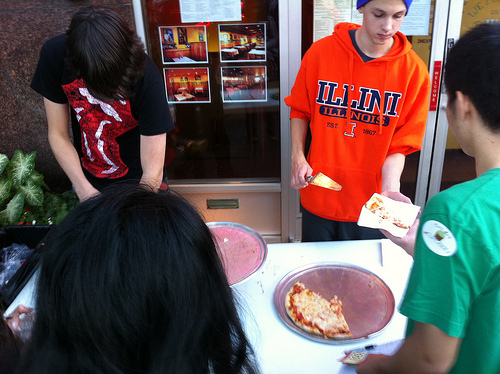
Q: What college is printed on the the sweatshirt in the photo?
A: Illinois.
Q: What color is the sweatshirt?
A: Orange.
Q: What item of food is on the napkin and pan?
A: Pizza.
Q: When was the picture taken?
A: Daytime.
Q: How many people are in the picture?
A: Four.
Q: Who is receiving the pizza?
A: Person with Green Shirt.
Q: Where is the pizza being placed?
A: Hand.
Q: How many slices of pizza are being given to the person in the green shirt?
A: One.